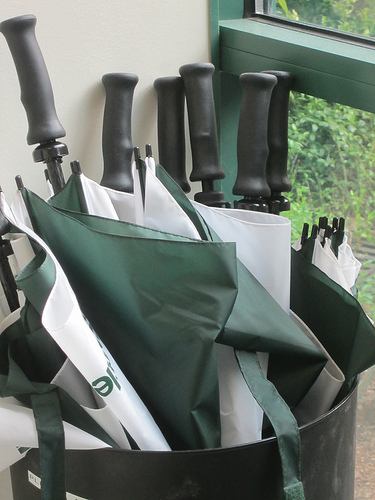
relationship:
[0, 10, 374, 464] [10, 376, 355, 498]
umbrella on barrel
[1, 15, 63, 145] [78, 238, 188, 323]
handle on umbrella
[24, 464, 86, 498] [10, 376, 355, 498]
sticker on barrel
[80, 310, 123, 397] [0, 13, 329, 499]
writing on umbrella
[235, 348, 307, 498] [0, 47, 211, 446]
ribbon on umbrella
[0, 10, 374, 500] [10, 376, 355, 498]
umbrella in barrel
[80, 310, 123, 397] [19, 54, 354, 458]
writing on umbrella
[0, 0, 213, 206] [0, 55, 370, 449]
wall behind umbrellas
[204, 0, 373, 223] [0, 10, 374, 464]
window frame behind umbrella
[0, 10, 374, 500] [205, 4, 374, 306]
umbrella next to window